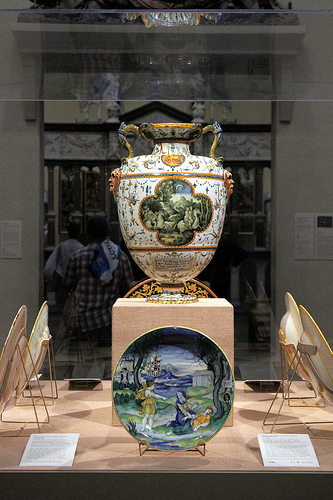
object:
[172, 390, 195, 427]
person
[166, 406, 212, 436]
person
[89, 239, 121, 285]
jersey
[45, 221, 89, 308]
man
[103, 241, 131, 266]
shoulder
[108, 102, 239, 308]
vase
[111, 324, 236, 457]
artwork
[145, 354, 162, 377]
ship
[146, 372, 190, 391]
waters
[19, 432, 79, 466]
paper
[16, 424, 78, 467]
placards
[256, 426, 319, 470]
placards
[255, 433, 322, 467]
paper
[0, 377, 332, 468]
display table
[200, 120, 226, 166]
handle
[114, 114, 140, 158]
handle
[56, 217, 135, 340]
reflection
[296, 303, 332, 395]
rim plates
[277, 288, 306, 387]
rim plates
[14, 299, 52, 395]
rim plates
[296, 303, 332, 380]
plate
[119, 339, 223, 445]
painting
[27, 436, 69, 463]
text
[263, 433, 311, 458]
text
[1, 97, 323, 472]
display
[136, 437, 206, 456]
rack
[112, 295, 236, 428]
block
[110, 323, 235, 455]
plate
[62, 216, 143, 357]
gentleman